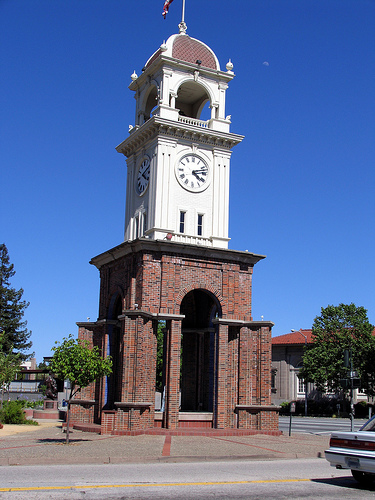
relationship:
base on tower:
[62, 250, 283, 433] [115, 0, 247, 241]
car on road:
[324, 413, 375, 483] [0, 456, 375, 496]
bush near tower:
[48, 334, 113, 443] [115, 29, 244, 248]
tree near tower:
[297, 302, 374, 417] [115, 29, 244, 248]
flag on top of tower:
[160, 0, 176, 24] [115, 0, 247, 241]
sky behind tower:
[0, 0, 374, 367] [115, 29, 244, 248]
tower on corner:
[115, 29, 244, 248] [3, 404, 352, 467]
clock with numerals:
[171, 149, 211, 196] [179, 153, 204, 167]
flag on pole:
[160, 0, 176, 24] [176, 1, 192, 22]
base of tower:
[70, 256, 290, 438] [115, 29, 244, 248]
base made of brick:
[70, 256, 290, 438] [204, 269, 238, 288]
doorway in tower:
[172, 284, 230, 419] [115, 29, 244, 248]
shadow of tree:
[37, 434, 93, 450] [41, 335, 118, 442]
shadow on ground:
[37, 434, 93, 450] [2, 418, 374, 474]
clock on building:
[171, 149, 217, 196] [62, 32, 282, 436]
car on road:
[324, 413, 363, 471] [1, 462, 361, 498]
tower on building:
[115, 29, 244, 248] [62, 32, 282, 436]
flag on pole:
[160, 0, 175, 17] [180, 3, 184, 28]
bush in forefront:
[48, 334, 113, 443] [23, 334, 312, 458]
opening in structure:
[179, 288, 221, 414] [67, 29, 284, 433]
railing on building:
[178, 117, 210, 126] [62, 32, 282, 436]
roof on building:
[272, 328, 360, 345] [275, 348, 363, 410]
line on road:
[4, 476, 351, 489] [1, 462, 361, 498]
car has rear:
[324, 413, 375, 483] [325, 431, 363, 469]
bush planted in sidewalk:
[48, 334, 113, 443] [10, 429, 322, 454]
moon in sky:
[260, 58, 270, 68] [239, 8, 362, 252]